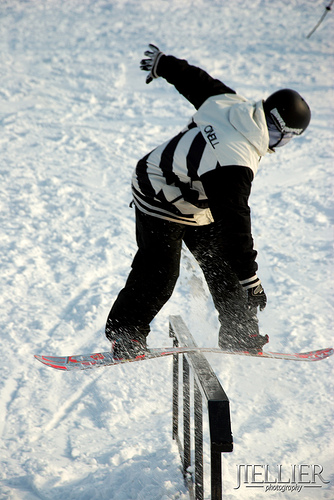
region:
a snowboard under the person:
[30, 338, 332, 375]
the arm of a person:
[199, 163, 263, 279]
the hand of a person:
[240, 277, 271, 316]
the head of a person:
[259, 82, 315, 158]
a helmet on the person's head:
[261, 84, 312, 139]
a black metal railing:
[156, 310, 243, 498]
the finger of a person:
[147, 41, 163, 52]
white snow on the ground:
[0, 0, 333, 497]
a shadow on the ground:
[0, 441, 192, 498]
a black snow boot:
[213, 312, 272, 354]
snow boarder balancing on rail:
[61, 66, 310, 370]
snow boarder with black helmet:
[220, 71, 307, 169]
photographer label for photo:
[221, 451, 328, 494]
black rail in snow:
[162, 323, 239, 491]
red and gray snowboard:
[29, 306, 330, 375]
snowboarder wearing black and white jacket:
[119, 74, 296, 213]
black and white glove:
[125, 44, 173, 86]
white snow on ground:
[27, 136, 91, 221]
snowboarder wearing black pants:
[91, 186, 284, 372]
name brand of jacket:
[195, 111, 235, 167]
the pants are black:
[127, 244, 175, 330]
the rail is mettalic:
[172, 378, 238, 482]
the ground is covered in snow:
[33, 425, 162, 494]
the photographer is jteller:
[231, 450, 328, 484]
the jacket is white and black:
[146, 125, 237, 195]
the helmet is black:
[266, 86, 312, 122]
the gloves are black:
[247, 291, 271, 309]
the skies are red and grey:
[48, 350, 331, 372]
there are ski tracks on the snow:
[10, 314, 97, 406]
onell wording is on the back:
[200, 121, 227, 150]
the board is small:
[26, 330, 317, 434]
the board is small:
[39, 324, 161, 410]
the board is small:
[40, 299, 222, 469]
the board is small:
[16, 266, 154, 377]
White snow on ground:
[46, 145, 82, 187]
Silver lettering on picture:
[230, 462, 333, 483]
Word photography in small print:
[260, 485, 308, 491]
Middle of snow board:
[153, 329, 216, 361]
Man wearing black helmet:
[265, 83, 313, 138]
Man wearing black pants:
[125, 228, 168, 301]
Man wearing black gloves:
[245, 285, 268, 316]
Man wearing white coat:
[204, 103, 221, 123]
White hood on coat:
[231, 95, 265, 149]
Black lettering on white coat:
[202, 122, 222, 152]